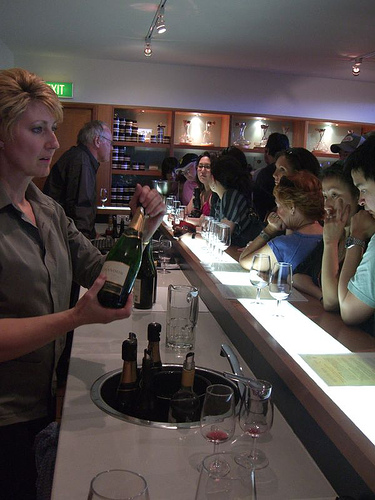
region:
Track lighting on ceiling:
[134, 0, 172, 58]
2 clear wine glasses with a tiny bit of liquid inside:
[197, 380, 276, 474]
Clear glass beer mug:
[163, 281, 199, 353]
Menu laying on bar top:
[294, 344, 373, 389]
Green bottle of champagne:
[97, 192, 146, 305]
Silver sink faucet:
[218, 335, 254, 411]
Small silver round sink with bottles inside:
[91, 361, 241, 429]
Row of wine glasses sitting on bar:
[200, 211, 231, 266]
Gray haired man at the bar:
[79, 118, 115, 166]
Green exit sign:
[39, 80, 73, 98]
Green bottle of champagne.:
[106, 196, 198, 358]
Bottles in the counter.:
[133, 319, 249, 420]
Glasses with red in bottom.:
[186, 393, 286, 454]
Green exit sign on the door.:
[45, 58, 71, 101]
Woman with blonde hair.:
[5, 71, 120, 197]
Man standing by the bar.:
[81, 120, 156, 223]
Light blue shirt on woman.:
[253, 221, 334, 288]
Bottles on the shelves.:
[109, 110, 277, 148]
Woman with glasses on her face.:
[188, 140, 211, 178]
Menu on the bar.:
[228, 274, 313, 310]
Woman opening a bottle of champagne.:
[0, 65, 168, 321]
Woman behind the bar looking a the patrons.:
[1, 69, 166, 498]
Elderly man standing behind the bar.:
[43, 118, 115, 241]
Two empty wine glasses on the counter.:
[197, 377, 274, 480]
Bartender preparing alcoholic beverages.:
[1, 68, 169, 497]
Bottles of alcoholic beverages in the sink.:
[100, 321, 236, 427]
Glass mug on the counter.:
[165, 282, 200, 352]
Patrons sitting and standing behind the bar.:
[159, 129, 373, 325]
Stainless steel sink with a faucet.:
[88, 341, 251, 429]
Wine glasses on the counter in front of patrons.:
[196, 215, 293, 321]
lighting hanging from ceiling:
[132, 1, 185, 69]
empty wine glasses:
[198, 375, 279, 487]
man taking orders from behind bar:
[66, 115, 129, 258]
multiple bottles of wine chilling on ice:
[114, 317, 228, 435]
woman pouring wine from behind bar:
[3, 58, 177, 420]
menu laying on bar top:
[293, 326, 374, 421]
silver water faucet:
[203, 335, 253, 426]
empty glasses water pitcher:
[160, 273, 207, 364]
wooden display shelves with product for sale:
[106, 104, 189, 210]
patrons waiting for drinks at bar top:
[171, 144, 373, 310]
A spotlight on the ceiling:
[136, 11, 189, 59]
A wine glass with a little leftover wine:
[242, 378, 268, 469]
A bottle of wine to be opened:
[97, 196, 150, 311]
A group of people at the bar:
[194, 153, 374, 247]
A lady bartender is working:
[5, 74, 75, 297]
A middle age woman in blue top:
[244, 177, 320, 263]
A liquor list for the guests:
[304, 348, 374, 382]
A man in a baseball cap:
[334, 128, 358, 162]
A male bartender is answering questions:
[59, 114, 113, 193]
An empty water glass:
[160, 279, 199, 351]